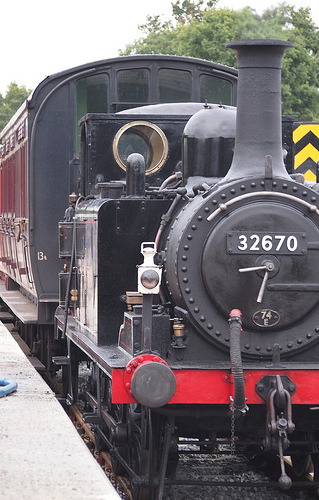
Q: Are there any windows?
A: Yes, there is a window.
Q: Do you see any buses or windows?
A: Yes, there is a window.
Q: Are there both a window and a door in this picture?
A: No, there is a window but no doors.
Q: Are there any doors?
A: No, there are no doors.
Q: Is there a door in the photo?
A: No, there are no doors.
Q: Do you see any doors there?
A: No, there are no doors.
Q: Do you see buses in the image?
A: No, there are no buses.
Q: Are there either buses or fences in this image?
A: No, there are no buses or fences.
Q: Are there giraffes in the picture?
A: Yes, there is a giraffe.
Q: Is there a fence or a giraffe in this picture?
A: Yes, there is a giraffe.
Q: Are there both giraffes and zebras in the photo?
A: No, there is a giraffe but no zebras.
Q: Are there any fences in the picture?
A: No, there are no fences.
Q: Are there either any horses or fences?
A: No, there are no fences or horses.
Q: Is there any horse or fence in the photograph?
A: No, there are no fences or horses.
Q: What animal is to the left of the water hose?
A: The animal is a giraffe.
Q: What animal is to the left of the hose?
A: The animal is a giraffe.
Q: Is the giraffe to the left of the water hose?
A: Yes, the giraffe is to the left of the water hose.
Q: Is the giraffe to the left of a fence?
A: No, the giraffe is to the left of the water hose.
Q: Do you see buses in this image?
A: No, there are no buses.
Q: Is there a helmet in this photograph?
A: No, there are no helmets.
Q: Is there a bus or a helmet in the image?
A: No, there are no helmets or buses.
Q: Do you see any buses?
A: No, there are no buses.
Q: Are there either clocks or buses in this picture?
A: No, there are no buses or clocks.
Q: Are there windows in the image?
A: Yes, there is a window.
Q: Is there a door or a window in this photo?
A: Yes, there is a window.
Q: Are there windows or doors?
A: Yes, there is a window.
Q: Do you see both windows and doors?
A: No, there is a window but no doors.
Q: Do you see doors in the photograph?
A: No, there are no doors.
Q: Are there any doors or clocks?
A: No, there are no doors or clocks.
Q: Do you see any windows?
A: Yes, there are windows.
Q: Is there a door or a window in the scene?
A: Yes, there are windows.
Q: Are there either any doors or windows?
A: Yes, there are windows.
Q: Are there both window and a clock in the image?
A: No, there are windows but no clocks.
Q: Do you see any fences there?
A: No, there are no fences.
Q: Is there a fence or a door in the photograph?
A: No, there are no fences or doors.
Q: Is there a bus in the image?
A: No, there are no buses.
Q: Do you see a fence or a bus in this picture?
A: No, there are no buses or fences.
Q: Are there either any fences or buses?
A: No, there are no buses or fences.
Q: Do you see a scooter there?
A: No, there are no scooters.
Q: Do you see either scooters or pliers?
A: No, there are no scooters or pliers.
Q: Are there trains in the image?
A: Yes, there is a train.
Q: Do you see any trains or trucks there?
A: Yes, there is a train.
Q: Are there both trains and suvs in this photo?
A: No, there is a train but no suvs.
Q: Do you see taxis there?
A: No, there are no taxis.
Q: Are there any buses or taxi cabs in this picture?
A: No, there are no taxi cabs or buses.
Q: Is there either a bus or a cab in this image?
A: No, there are no taxis or buses.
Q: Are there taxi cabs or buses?
A: No, there are no taxi cabs or buses.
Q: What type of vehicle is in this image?
A: The vehicle is a train.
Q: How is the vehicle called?
A: The vehicle is a train.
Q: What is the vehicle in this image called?
A: The vehicle is a train.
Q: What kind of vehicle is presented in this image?
A: The vehicle is a train.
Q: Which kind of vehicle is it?
A: The vehicle is a train.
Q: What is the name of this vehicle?
A: This is a train.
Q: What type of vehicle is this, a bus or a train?
A: This is a train.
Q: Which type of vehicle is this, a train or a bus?
A: This is a train.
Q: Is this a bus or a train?
A: This is a train.